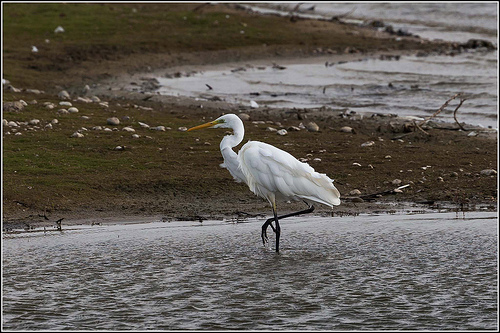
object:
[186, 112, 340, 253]
bird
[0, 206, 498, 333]
water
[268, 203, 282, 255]
leg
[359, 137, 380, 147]
rocks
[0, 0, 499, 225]
grass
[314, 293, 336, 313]
ice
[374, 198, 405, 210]
mud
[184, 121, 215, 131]
beak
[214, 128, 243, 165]
neck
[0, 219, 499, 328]
waves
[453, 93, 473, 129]
branches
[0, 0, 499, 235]
shore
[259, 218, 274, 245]
claw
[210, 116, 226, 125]
eye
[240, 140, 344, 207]
feathers